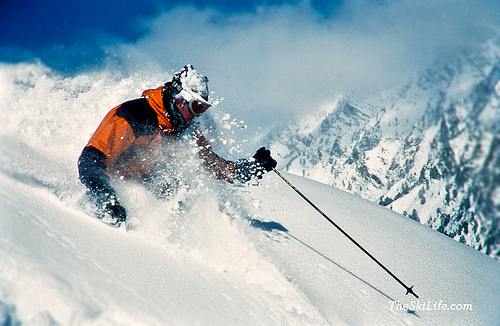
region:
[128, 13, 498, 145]
the fog is above the mountains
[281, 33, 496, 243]
mountains are covered with snow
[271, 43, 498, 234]
rocks of mountains are visible between the snow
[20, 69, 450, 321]
the person is sliding down along the slope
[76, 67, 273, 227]
the guy is wearing gloves in his hand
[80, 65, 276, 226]
the person is wearing goggles to protect his eyes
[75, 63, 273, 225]
the man is wearing warm coat to protect himself from cold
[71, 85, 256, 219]
orange and black jacket for cold weather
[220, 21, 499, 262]
large rocky mountain covered in snow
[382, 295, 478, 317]
white lettering superimposed above image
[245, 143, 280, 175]
black glove for winter weather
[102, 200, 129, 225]
black glove for winter weather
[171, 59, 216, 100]
cold weather hat covered in snow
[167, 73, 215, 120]
pair of grey goggles with black strap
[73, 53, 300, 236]
person skiing down a snowy slope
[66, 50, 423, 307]
person carrying a ski pole down a slope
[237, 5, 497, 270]
large rocky mountain covered in snow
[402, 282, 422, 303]
tip of a black metal ski pole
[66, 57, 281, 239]
man with snow flying around him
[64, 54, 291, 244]
man wearing an orange and black jacket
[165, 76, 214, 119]
grey goggles with black strap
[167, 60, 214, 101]
black winter hat covered in snow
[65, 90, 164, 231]
arm of a person skiing in the snow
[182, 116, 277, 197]
arm of a person skiing in the snow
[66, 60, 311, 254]
person wearing hat and goggles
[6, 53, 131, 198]
large plume of white snow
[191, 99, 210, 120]
The snowgoggles the skier is wearing.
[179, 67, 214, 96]
The hat the skier is wearing.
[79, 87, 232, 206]
The jacket the skier is wearing.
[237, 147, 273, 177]
The glove on the skier's right hand.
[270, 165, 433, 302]
The ski pole in the skier's right hand.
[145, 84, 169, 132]
The hood on the skier's jacket.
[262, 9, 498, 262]
The snow covered mountain on the right.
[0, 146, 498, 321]
The hill the skier is skiing on.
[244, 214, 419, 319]
The shadow of the skier's hand and ski pole.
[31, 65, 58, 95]
snow splat behind guy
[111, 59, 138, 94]
snow splat behind guy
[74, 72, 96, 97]
snow splat behind guy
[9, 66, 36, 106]
snow splat behind guy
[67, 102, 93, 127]
snow splat behind guy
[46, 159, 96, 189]
snow splat behind guy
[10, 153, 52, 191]
snow splat behind guy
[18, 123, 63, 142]
snow splat behind guy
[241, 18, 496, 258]
mountain peak covered in snow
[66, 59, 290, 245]
man skiing down a snowy slope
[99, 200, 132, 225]
black winter weather glove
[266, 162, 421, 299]
The ski pole in the hand of the man.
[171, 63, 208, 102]
The snow on the cap.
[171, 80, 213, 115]
The googles on the skier.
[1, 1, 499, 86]
deep blue sky with misty clouds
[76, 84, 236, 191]
orange and black ski jacket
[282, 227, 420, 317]
shadow of ski pole on snow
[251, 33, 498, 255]
rocky snow covered mountain side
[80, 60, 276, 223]
Man skiing in snow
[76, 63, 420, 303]
man holding ski pole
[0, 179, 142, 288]
tracks in the snow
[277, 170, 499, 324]
undisturbed snow near skier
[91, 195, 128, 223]
black glove on skier's hand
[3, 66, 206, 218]
snow churned up by skier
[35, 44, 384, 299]
The person is skiing